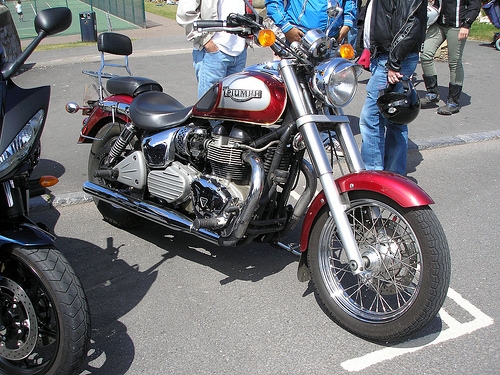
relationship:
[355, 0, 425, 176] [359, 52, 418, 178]
man wearing jeans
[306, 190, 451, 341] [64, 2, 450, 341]
front wheel on motorcycle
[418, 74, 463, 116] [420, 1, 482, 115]
boots on person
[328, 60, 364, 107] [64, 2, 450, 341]
headlight on motorcycle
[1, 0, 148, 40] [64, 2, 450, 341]
fence behind motorcycle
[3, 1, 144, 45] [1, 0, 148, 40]
tennis court behind fence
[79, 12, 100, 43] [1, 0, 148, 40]
trash can next to fence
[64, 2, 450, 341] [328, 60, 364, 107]
motorcycle has a headlight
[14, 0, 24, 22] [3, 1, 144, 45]
person on tennis court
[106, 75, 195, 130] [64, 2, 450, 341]
seat on motorcycle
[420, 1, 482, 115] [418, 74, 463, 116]
person wearing boots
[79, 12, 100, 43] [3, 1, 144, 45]
trash can near tennis court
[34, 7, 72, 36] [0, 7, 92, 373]
mirror on motorcycle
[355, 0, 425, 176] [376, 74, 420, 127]
man holding helmet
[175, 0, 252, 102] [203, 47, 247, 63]
man has pockets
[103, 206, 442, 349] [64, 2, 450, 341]
shadow from motorcycle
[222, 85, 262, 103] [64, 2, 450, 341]
logo on motorcycle